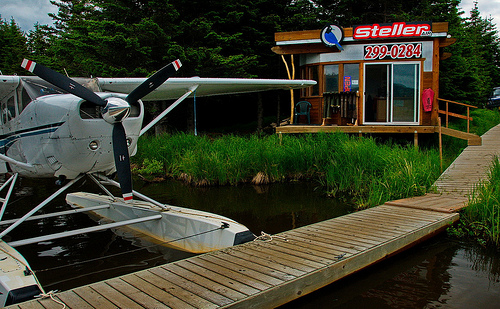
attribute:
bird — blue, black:
[323, 24, 353, 61]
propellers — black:
[23, 49, 173, 198]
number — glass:
[362, 42, 424, 61]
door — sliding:
[359, 57, 424, 127]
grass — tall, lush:
[140, 129, 447, 206]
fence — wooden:
[426, 87, 486, 148]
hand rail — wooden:
[436, 95, 478, 132]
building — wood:
[270, 12, 480, 147]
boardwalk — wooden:
[2, 122, 498, 307]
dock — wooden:
[1, 121, 498, 307]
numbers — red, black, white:
[346, 35, 428, 62]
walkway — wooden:
[318, 213, 457, 248]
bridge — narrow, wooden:
[186, 235, 318, 301]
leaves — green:
[28, 13, 278, 74]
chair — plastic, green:
[290, 97, 314, 124]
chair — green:
[290, 101, 310, 121]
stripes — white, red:
[168, 59, 185, 68]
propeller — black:
[17, 50, 190, 206]